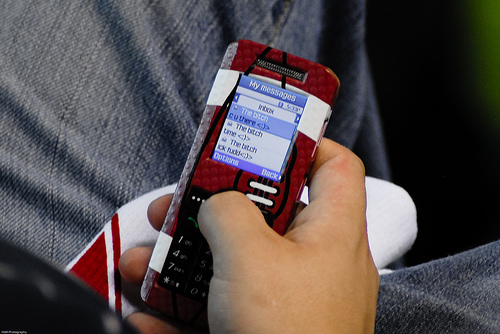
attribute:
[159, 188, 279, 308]
keypad — phone's, on surface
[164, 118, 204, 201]
dots — bumpy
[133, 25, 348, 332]
cell phone — old,  old 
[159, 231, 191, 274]
numbers — white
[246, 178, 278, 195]
stripe — white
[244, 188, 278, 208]
stripe — white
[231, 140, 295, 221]
border — black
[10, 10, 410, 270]
jeans — user's, denim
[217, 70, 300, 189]
words/screen — glowing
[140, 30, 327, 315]
device — resembling football 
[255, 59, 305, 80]
speaker — audio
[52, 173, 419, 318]
object — white and red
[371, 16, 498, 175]
space — dark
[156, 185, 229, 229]
panel — black